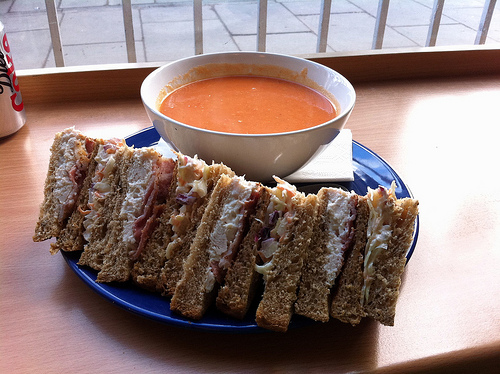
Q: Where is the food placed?
A: On the table.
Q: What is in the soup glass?
A: Soup.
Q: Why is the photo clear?
A: Its daytime.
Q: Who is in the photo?
A: Nobody.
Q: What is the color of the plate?
A: Blue.